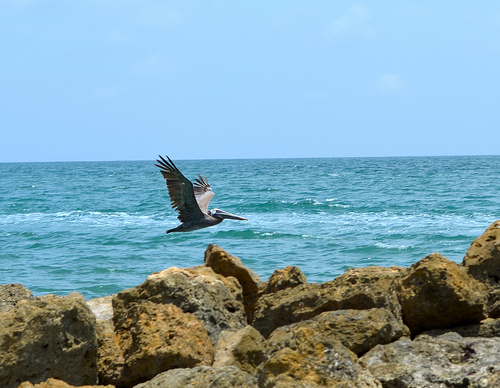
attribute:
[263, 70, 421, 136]
sky — blue, cloudless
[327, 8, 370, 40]
cloud — white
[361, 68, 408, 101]
cloud — white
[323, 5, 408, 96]
clouds — white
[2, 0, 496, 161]
sky — blue, clear, open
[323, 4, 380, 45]
cloud — white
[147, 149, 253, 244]
seabird — gray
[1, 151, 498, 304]
water — calm, blue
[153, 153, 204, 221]
wing — outstretched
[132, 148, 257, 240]
bird — long beak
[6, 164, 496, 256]
water — large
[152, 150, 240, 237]
wings — gray, outspread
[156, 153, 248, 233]
seabird — gray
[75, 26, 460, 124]
sky — blue, in the distance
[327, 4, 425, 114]
clouds — white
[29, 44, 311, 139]
sky — blue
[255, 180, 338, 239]
wave — small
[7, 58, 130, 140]
clouds — white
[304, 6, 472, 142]
clouds — white